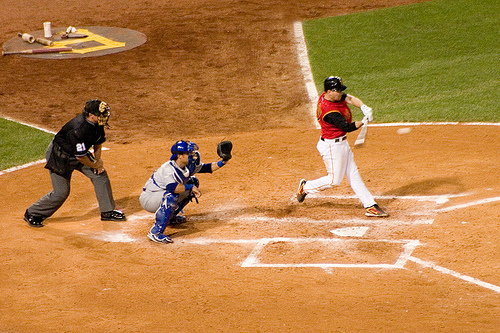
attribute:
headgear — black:
[323, 74, 348, 89]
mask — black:
[98, 102, 111, 128]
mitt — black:
[217, 141, 234, 161]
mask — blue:
[188, 143, 200, 172]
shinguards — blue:
[152, 194, 194, 236]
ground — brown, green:
[1, 0, 498, 331]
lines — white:
[122, 186, 499, 303]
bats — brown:
[1, 31, 89, 59]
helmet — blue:
[172, 141, 189, 156]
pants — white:
[305, 137, 378, 206]